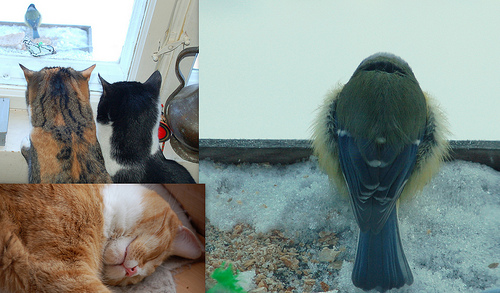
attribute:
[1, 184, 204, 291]
cat — sleeping, orange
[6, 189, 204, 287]
cat — sleeping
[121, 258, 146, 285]
nose — pink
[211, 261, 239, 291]
feather — green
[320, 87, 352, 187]
wings — fluffy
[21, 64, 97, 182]
cat — brown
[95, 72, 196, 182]
cat — black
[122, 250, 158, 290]
eyes — closed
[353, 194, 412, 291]
tail — blue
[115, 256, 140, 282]
nose — pink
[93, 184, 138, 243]
patch — white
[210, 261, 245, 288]
object — green, furry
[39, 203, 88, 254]
kitten fur — dark orange